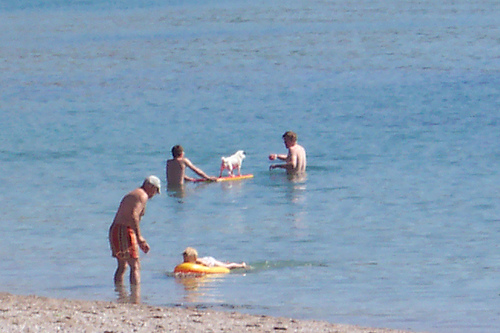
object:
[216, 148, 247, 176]
dog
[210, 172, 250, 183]
paddle board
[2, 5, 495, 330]
water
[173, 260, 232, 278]
floating device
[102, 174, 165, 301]
man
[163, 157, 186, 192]
body of water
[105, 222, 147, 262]
swim trunks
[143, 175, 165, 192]
baseball cap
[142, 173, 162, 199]
head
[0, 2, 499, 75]
ripples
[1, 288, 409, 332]
ground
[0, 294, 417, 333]
sand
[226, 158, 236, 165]
fur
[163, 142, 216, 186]
people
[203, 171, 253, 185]
surfboard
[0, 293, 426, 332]
beach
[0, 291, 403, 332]
tracks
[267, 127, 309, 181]
person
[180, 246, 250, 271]
person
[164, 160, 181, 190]
back turned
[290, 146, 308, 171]
back turned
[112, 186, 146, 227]
back turned